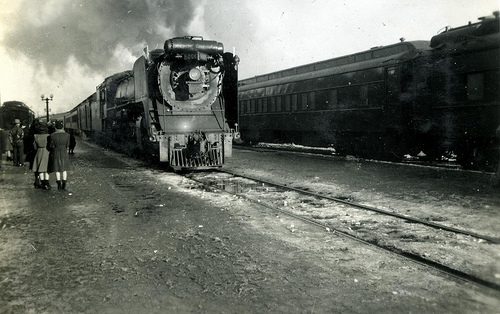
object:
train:
[236, 20, 499, 170]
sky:
[0, 1, 497, 116]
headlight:
[159, 130, 233, 171]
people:
[68, 133, 75, 154]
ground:
[18, 188, 176, 264]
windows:
[236, 79, 387, 117]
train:
[62, 36, 240, 173]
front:
[149, 36, 239, 173]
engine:
[63, 35, 240, 171]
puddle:
[179, 170, 499, 265]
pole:
[40, 93, 53, 126]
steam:
[0, 1, 261, 85]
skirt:
[51, 147, 70, 172]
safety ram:
[168, 132, 224, 172]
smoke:
[0, 0, 261, 89]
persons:
[20, 119, 34, 160]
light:
[188, 68, 201, 81]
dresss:
[46, 121, 77, 191]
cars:
[232, 37, 430, 160]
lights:
[40, 94, 52, 101]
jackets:
[50, 130, 71, 173]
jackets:
[32, 134, 48, 173]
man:
[12, 119, 27, 168]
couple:
[29, 122, 53, 190]